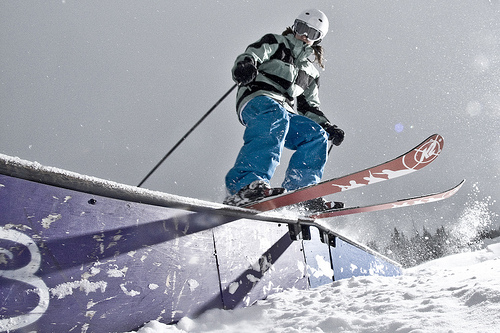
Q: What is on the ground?
A: Snow.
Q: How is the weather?
A: Cloudy.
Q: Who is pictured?
A: Skier.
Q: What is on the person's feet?
A: Skis.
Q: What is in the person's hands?
A: Ski poles.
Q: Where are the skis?
A: Skier's feet.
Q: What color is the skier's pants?
A: Blue.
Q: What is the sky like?
A: Clear.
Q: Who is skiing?
A: A skier.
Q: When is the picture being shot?
A: Daytime.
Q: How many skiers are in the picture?
A: One.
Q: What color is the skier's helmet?
A: White.